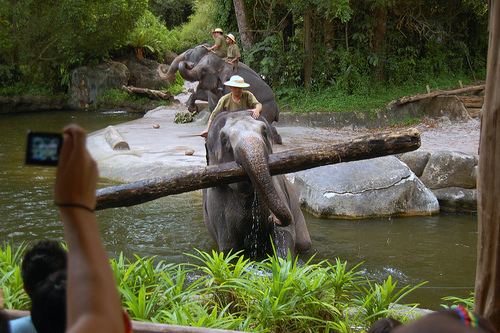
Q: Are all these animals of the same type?
A: Yes, all the animals are elephants.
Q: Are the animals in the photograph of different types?
A: No, all the animals are elephants.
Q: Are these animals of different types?
A: No, all the animals are elephants.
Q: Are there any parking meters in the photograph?
A: No, there are no parking meters.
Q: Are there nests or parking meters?
A: No, there are no parking meters or nests.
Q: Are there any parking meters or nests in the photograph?
A: No, there are no parking meters or nests.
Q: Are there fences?
A: No, there are no fences.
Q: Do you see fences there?
A: No, there are no fences.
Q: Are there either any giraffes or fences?
A: No, there are no fences or giraffes.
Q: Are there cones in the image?
A: No, there are no cones.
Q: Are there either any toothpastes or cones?
A: No, there are no cones or toothpastes.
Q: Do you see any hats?
A: Yes, there is a hat.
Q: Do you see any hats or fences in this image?
A: Yes, there is a hat.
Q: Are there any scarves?
A: No, there are no scarves.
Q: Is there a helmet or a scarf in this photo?
A: No, there are no scarves or helmets.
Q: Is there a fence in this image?
A: No, there are no fences.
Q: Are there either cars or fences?
A: No, there are no fences or cars.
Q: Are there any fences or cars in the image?
A: No, there are no fences or cars.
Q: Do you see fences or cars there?
A: No, there are no fences or cars.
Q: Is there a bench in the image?
A: No, there are no benches.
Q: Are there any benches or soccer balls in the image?
A: No, there are no benches or soccer balls.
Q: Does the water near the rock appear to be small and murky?
A: Yes, the water is small and murky.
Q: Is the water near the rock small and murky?
A: Yes, the water is small and murky.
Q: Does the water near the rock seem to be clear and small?
A: No, the water is small but murky.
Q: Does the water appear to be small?
A: Yes, the water is small.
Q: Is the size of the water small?
A: Yes, the water is small.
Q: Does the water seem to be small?
A: Yes, the water is small.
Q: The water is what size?
A: The water is small.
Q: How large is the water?
A: The water is small.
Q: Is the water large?
A: No, the water is small.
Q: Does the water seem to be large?
A: No, the water is small.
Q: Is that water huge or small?
A: The water is small.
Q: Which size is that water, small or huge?
A: The water is small.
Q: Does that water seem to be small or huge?
A: The water is small.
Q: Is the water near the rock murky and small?
A: Yes, the water is murky and small.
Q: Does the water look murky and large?
A: No, the water is murky but small.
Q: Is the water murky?
A: Yes, the water is murky.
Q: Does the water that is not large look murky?
A: Yes, the water is murky.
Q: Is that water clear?
A: No, the water is murky.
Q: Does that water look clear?
A: No, the water is murky.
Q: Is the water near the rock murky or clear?
A: The water is murky.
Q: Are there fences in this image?
A: No, there are no fences.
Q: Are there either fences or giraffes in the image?
A: No, there are no fences or giraffes.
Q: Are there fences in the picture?
A: No, there are no fences.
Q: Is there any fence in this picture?
A: No, there are no fences.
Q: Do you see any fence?
A: No, there are no fences.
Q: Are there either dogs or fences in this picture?
A: No, there are no fences or dogs.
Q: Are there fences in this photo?
A: No, there are no fences.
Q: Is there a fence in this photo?
A: No, there are no fences.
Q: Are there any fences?
A: No, there are no fences.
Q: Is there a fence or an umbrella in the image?
A: No, there are no fences or umbrellas.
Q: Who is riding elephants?
A: The people are riding elephants.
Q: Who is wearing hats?
A: The people are wearing hats.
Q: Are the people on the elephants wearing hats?
A: Yes, the people are wearing hats.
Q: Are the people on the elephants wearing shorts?
A: No, the people are wearing hats.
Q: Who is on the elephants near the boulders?
A: The people are on the elephants.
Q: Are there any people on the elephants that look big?
A: Yes, there are people on the elephants.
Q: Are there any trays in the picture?
A: No, there are no trays.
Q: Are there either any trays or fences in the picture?
A: No, there are no trays or fences.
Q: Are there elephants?
A: Yes, there are elephants.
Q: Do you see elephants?
A: Yes, there are elephants.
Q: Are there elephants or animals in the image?
A: Yes, there are elephants.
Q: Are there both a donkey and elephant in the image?
A: No, there are elephants but no donkeys.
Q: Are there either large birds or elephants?
A: Yes, there are large elephants.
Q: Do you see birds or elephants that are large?
A: Yes, the elephants are large.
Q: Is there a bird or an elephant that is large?
A: Yes, the elephants are large.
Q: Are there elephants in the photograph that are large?
A: Yes, there are large elephants.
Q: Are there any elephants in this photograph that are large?
A: Yes, there are elephants that are large.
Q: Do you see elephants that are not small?
A: Yes, there are large elephants.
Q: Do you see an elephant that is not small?
A: Yes, there are large elephants.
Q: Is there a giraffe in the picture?
A: No, there are no giraffes.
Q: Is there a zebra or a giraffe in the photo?
A: No, there are no giraffes or zebras.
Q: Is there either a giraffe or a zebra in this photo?
A: No, there are no giraffes or zebras.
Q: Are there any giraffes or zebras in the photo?
A: No, there are no giraffes or zebras.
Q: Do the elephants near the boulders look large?
A: Yes, the elephants are large.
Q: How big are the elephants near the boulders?
A: The elephants are large.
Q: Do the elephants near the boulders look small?
A: No, the elephants are large.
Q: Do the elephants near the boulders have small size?
A: No, the elephants are large.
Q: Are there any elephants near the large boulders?
A: Yes, there are elephants near the boulders.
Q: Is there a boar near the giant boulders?
A: No, there are elephants near the boulders.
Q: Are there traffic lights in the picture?
A: No, there are no traffic lights.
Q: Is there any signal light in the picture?
A: No, there are no traffic lights.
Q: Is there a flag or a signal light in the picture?
A: No, there are no traffic lights or flags.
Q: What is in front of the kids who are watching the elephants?
A: The plants are in front of the children.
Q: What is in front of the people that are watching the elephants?
A: The plants are in front of the children.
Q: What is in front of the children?
A: The plants are in front of the children.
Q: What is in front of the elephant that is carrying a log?
A: The plants are in front of the elephant.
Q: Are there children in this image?
A: Yes, there are children.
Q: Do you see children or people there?
A: Yes, there are children.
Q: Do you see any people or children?
A: Yes, there are children.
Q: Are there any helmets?
A: No, there are no helmets.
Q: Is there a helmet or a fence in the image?
A: No, there are no helmets or fences.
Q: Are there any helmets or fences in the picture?
A: No, there are no helmets or fences.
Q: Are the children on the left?
A: Yes, the children are on the left of the image.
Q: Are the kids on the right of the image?
A: No, the kids are on the left of the image.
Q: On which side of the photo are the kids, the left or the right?
A: The kids are on the left of the image.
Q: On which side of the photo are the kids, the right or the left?
A: The kids are on the left of the image.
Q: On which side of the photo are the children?
A: The children are on the left of the image.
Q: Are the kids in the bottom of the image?
A: Yes, the kids are in the bottom of the image.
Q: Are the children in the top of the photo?
A: No, the children are in the bottom of the image.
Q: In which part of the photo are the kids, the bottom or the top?
A: The kids are in the bottom of the image.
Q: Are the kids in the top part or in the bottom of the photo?
A: The kids are in the bottom of the image.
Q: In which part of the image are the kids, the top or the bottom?
A: The kids are in the bottom of the image.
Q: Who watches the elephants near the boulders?
A: The children watch the elephants.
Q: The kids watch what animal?
A: The kids watch the elephants.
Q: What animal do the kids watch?
A: The kids watch the elephants.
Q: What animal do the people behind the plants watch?
A: The kids watch the elephants.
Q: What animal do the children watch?
A: The kids watch the elephants.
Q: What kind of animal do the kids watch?
A: The kids watch the elephants.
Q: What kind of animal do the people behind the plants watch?
A: The kids watch the elephants.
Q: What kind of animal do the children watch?
A: The kids watch the elephants.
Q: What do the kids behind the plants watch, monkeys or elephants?
A: The kids watch elephants.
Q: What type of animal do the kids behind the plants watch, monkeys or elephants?
A: The kids watch elephants.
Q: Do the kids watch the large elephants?
A: Yes, the kids watch the elephants.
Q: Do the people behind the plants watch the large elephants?
A: Yes, the kids watch the elephants.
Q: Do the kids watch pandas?
A: No, the kids watch the elephants.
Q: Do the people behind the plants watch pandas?
A: No, the kids watch the elephants.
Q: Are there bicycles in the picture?
A: No, there are no bicycles.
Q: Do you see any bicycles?
A: No, there are no bicycles.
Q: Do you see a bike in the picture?
A: No, there are no bikes.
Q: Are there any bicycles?
A: No, there are no bicycles.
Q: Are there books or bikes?
A: No, there are no bikes or books.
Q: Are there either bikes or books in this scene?
A: No, there are no bikes or books.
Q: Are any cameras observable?
A: Yes, there is a camera.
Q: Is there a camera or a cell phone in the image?
A: Yes, there is a camera.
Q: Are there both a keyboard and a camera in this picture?
A: No, there is a camera but no keyboards.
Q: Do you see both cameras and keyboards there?
A: No, there is a camera but no keyboards.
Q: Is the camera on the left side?
A: Yes, the camera is on the left of the image.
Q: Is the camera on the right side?
A: No, the camera is on the left of the image.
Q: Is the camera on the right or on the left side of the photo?
A: The camera is on the left of the image.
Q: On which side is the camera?
A: The camera is on the left of the image.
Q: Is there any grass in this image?
A: Yes, there is grass.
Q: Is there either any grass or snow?
A: Yes, there is grass.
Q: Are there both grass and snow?
A: No, there is grass but no snow.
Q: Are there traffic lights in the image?
A: No, there are no traffic lights.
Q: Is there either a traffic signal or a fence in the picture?
A: No, there are no traffic lights or fences.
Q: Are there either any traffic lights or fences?
A: No, there are no traffic lights or fences.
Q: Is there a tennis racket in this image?
A: No, there are no rackets.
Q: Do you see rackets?
A: No, there are no rackets.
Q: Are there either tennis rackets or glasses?
A: No, there are no tennis rackets or glasses.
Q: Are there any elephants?
A: Yes, there is an elephant.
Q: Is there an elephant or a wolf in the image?
A: Yes, there is an elephant.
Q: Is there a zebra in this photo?
A: No, there are no zebras.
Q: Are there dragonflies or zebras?
A: No, there are no zebras or dragonflies.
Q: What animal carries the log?
A: The elephant carries the log.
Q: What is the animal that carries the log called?
A: The animal is an elephant.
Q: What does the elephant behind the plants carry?
A: The elephant carries a log.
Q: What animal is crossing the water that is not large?
A: The elephant is crossing the water.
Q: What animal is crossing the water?
A: The elephant is crossing the water.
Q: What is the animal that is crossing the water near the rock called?
A: The animal is an elephant.